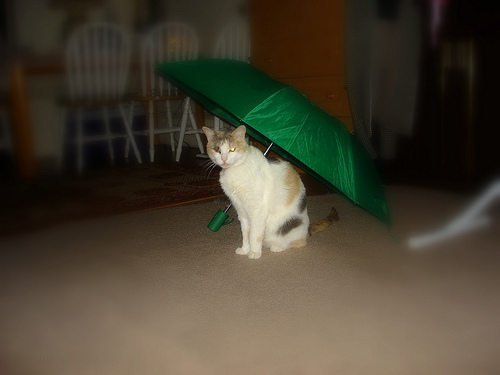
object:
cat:
[192, 115, 345, 257]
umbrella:
[152, 44, 397, 228]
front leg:
[400, 186, 500, 250]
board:
[395, 111, 498, 183]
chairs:
[56, 14, 246, 162]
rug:
[3, 189, 500, 372]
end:
[3, 50, 35, 172]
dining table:
[10, 46, 286, 162]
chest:
[248, 2, 348, 142]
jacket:
[372, 4, 421, 133]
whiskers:
[191, 156, 261, 175]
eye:
[228, 143, 236, 151]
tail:
[303, 205, 342, 243]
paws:
[228, 241, 289, 259]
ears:
[195, 126, 253, 139]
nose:
[218, 152, 231, 160]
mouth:
[218, 160, 233, 168]